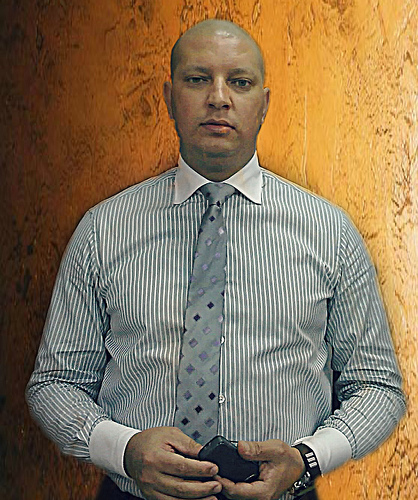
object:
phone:
[196, 434, 259, 487]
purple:
[194, 374, 204, 389]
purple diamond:
[203, 235, 212, 247]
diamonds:
[210, 275, 217, 283]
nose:
[203, 74, 232, 113]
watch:
[285, 442, 323, 499]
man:
[22, 15, 409, 499]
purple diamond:
[217, 224, 226, 236]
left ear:
[260, 84, 270, 122]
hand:
[120, 422, 228, 499]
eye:
[228, 78, 252, 89]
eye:
[184, 75, 207, 86]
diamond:
[193, 248, 198, 258]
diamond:
[192, 312, 200, 323]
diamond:
[187, 335, 198, 350]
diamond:
[200, 327, 212, 338]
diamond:
[194, 375, 207, 387]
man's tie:
[172, 182, 240, 444]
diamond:
[208, 363, 220, 376]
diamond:
[196, 348, 209, 365]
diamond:
[183, 363, 195, 376]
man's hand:
[214, 437, 304, 499]